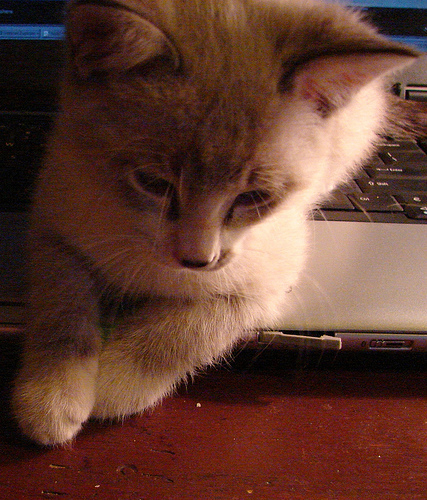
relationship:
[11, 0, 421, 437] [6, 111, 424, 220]
kitten on keyboard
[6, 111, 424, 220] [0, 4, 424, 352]
keyboard from laptop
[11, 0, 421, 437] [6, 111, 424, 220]
kitten on top of keyboard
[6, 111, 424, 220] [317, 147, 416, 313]
keyboard from laptop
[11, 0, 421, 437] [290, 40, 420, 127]
kitten has ear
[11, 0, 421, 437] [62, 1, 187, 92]
kitten has ear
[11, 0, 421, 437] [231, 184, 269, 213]
kitten has eye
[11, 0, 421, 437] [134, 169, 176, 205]
kitten has eye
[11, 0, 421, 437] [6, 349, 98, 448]
kitten has paw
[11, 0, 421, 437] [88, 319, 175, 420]
kitten has paw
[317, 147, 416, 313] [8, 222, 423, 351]
laptop has surface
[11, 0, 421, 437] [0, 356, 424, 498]
kitten looking table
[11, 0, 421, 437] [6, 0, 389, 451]
kitten has fur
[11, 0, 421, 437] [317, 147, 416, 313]
kitten on top of laptop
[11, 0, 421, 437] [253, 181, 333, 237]
kitten has whiskers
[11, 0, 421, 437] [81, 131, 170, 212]
kitten has whiskers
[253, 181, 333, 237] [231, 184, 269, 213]
whiskers are above eye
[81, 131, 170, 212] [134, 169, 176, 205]
whiskers are above eye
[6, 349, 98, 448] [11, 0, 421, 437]
paw in front of kitten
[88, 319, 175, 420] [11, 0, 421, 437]
paw in front of kitten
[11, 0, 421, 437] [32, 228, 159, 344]
kitten has whiskers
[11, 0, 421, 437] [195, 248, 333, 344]
kitten has whiskers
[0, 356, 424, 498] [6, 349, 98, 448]
table under paw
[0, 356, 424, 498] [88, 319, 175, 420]
table under paw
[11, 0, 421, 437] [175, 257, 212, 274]
kitten has nose